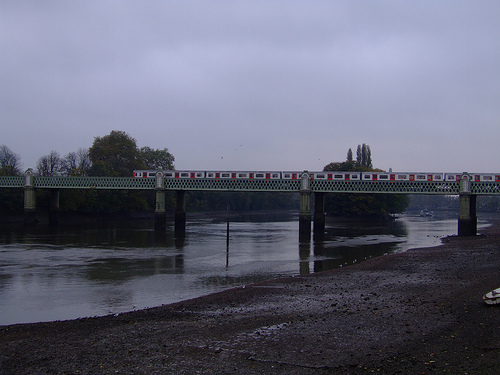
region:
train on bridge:
[95, 162, 483, 213]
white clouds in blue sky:
[365, 47, 449, 117]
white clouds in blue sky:
[249, 64, 274, 89]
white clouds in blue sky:
[302, 44, 364, 99]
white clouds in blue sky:
[200, 34, 260, 102]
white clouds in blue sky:
[20, 53, 88, 104]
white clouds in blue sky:
[197, 4, 252, 53]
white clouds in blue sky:
[347, 34, 407, 100]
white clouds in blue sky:
[180, 21, 248, 72]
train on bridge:
[127, 159, 462, 188]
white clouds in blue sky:
[45, 7, 94, 57]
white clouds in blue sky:
[192, 69, 241, 130]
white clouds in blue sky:
[400, 30, 452, 86]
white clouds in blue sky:
[397, 125, 432, 165]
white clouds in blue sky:
[57, 22, 160, 70]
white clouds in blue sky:
[266, 31, 302, 71]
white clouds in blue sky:
[370, 43, 402, 83]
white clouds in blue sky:
[128, 24, 188, 96]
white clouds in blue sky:
[101, 38, 226, 71]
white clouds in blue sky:
[369, 80, 472, 122]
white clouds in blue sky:
[223, 42, 280, 99]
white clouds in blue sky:
[123, 12, 178, 65]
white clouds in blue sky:
[66, 62, 124, 97]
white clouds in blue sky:
[191, 33, 276, 143]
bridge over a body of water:
[1, 167, 497, 374]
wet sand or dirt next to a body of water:
[0, 218, 499, 373]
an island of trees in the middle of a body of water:
[275, 129, 434, 254]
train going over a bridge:
[0, 150, 498, 254]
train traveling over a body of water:
[1, 148, 498, 373]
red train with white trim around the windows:
[125, 166, 498, 198]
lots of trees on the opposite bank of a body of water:
[1, 116, 498, 374]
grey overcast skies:
[0, 2, 498, 217]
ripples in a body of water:
[0, 187, 498, 374]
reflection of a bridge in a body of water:
[1, 158, 497, 374]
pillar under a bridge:
[298, 192, 313, 221]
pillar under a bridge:
[313, 192, 325, 219]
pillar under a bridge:
[457, 196, 476, 231]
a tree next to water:
[319, 142, 411, 218]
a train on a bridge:
[129, 166, 499, 191]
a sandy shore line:
[1, 219, 498, 374]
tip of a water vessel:
[483, 287, 499, 304]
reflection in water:
[222, 201, 231, 271]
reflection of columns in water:
[295, 243, 320, 280]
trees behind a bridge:
[0, 130, 178, 225]